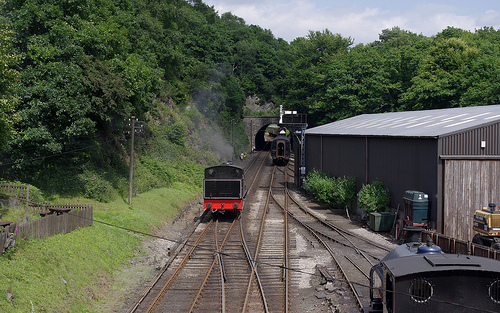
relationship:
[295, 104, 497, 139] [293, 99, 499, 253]
roof on building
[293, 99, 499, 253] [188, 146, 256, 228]
building by train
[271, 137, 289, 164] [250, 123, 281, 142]
train by tunnel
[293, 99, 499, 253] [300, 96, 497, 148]
building with roof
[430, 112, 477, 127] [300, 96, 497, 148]
stripes on roof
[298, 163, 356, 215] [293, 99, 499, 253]
bush by building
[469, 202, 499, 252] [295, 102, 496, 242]
tractor near building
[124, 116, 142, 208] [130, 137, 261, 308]
pole near tracks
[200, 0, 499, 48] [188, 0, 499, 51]
clouds are in sky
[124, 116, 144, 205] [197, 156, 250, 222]
pole left to train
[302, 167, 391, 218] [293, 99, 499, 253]
bush are on side of building